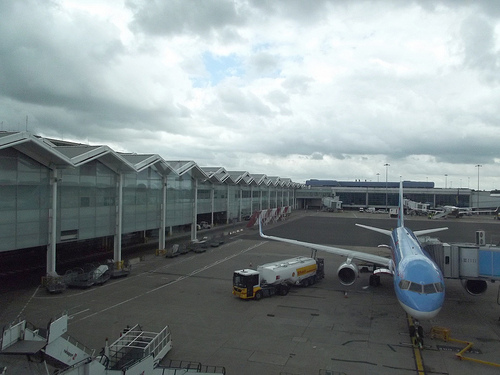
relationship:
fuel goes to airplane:
[224, 238, 338, 306] [236, 168, 499, 332]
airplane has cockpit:
[236, 168, 499, 332] [319, 198, 396, 289]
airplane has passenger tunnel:
[253, 174, 499, 323] [402, 213, 498, 290]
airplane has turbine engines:
[253, 174, 499, 323] [330, 246, 490, 296]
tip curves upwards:
[241, 208, 296, 248] [253, 210, 276, 243]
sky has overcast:
[2, 1, 499, 211] [3, 0, 498, 140]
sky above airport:
[2, 1, 499, 211] [3, 123, 497, 244]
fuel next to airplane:
[227, 246, 328, 305] [253, 174, 499, 323]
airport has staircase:
[3, 123, 497, 244] [65, 300, 237, 374]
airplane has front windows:
[253, 174, 499, 323] [393, 266, 456, 295]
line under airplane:
[389, 284, 435, 374] [253, 174, 499, 323]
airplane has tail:
[236, 168, 499, 332] [356, 188, 442, 258]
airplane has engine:
[236, 168, 499, 332] [330, 246, 490, 296]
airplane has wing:
[236, 168, 499, 332] [238, 199, 406, 270]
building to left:
[3, 123, 497, 244] [3, 114, 251, 265]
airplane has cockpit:
[236, 168, 499, 332] [378, 248, 456, 319]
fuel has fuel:
[227, 246, 328, 305] [227, 246, 328, 305]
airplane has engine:
[253, 174, 499, 323] [330, 246, 490, 296]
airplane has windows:
[236, 168, 499, 332] [378, 248, 456, 319]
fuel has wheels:
[227, 246, 328, 305] [249, 280, 310, 309]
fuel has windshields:
[227, 246, 328, 305] [229, 260, 260, 291]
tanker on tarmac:
[224, 238, 338, 306] [22, 200, 498, 355]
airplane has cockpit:
[253, 174, 499, 323] [378, 248, 456, 319]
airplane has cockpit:
[253, 174, 499, 323] [319, 198, 396, 289]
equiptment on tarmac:
[40, 224, 247, 301] [22, 200, 498, 355]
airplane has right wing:
[253, 174, 499, 323] [238, 199, 406, 270]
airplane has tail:
[253, 174, 499, 323] [356, 188, 442, 258]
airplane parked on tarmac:
[253, 174, 499, 323] [22, 200, 498, 355]